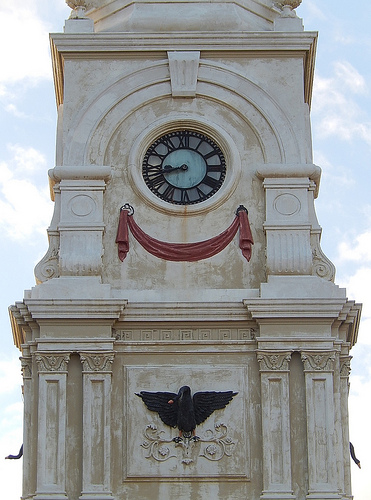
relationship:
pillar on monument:
[241, 288, 350, 499] [8, 0, 363, 499]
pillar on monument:
[19, 295, 132, 500] [8, 0, 363, 499]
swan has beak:
[133, 382, 241, 438] [165, 396, 175, 406]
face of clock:
[143, 132, 227, 204] [125, 111, 243, 215]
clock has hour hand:
[125, 111, 243, 215] [151, 162, 190, 176]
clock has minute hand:
[125, 111, 243, 215] [149, 160, 187, 182]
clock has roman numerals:
[125, 111, 243, 215] [143, 132, 225, 203]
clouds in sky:
[2, 141, 56, 240] [1, 1, 367, 319]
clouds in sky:
[0, 4, 56, 87] [1, 1, 367, 319]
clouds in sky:
[330, 228, 370, 301] [1, 1, 367, 319]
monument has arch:
[8, 0, 363, 499] [60, 56, 310, 170]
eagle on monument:
[133, 382, 241, 438] [8, 0, 363, 499]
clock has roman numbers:
[125, 111, 243, 215] [143, 132, 225, 203]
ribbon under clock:
[114, 203, 256, 264] [125, 111, 243, 215]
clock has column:
[125, 111, 243, 215] [50, 164, 115, 274]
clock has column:
[125, 111, 243, 215] [252, 160, 324, 275]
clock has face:
[125, 111, 243, 215] [143, 132, 227, 204]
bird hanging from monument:
[5, 438, 24, 463] [8, 0, 363, 499]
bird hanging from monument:
[347, 438, 361, 471] [8, 0, 363, 499]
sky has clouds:
[1, 1, 367, 319] [2, 141, 56, 240]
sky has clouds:
[1, 1, 367, 319] [0, 4, 56, 87]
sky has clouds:
[1, 1, 367, 319] [330, 228, 370, 301]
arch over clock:
[60, 56, 310, 170] [125, 111, 243, 215]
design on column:
[34, 349, 116, 372] [50, 164, 115, 274]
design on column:
[254, 346, 337, 372] [241, 288, 350, 499]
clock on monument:
[125, 111, 243, 215] [8, 0, 363, 499]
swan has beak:
[133, 382, 241, 444] [165, 396, 175, 406]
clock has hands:
[125, 111, 243, 215] [149, 160, 192, 180]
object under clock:
[114, 203, 256, 264] [125, 111, 243, 215]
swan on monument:
[133, 382, 241, 444] [8, 0, 363, 499]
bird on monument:
[347, 438, 361, 471] [8, 0, 363, 499]